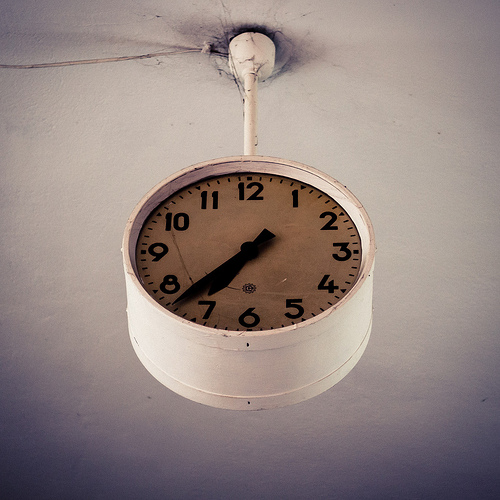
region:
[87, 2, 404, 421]
a white clock hanging from ceiling.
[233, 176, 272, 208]
number "twelve" showing on clock.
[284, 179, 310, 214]
number "one" showing on clock.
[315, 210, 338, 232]
number "two" showing on clock.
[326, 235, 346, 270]
number "three" showing on clock.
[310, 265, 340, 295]
number "four" showing on clock.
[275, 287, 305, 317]
number "five" showing on clock.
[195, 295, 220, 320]
number "seven" showing on clock.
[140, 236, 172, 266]
number "nine" showing on clock.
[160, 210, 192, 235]
number "ten" showing on clock.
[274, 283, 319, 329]
the number five in black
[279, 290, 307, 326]
the number five in black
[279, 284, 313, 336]
the number five in black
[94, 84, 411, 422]
a large white clock hanging from ceiling.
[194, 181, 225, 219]
the number "eleven" showing on clock.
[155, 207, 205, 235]
the number "ten" showing on clock.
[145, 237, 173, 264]
the number "nine" showing on clock.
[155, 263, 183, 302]
the number "eight" showing on clock.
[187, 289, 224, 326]
the number "seven" showing on clock.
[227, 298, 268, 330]
the number "six" showing on clock.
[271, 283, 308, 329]
the number "five" showing on clock.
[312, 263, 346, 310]
the number "four" showing on clock.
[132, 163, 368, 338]
the round face of a clock.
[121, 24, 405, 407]
A white clock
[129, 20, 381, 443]
A white clock hanging from the ceiling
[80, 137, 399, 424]
A round white clock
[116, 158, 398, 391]
A white clock with black hands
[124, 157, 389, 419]
A white clock with black numbers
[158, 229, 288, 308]
the hands of a clock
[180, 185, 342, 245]
the numbers of a clock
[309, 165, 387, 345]
the edge of a clock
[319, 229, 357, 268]
A black number "3"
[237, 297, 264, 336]
A black number "6"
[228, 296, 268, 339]
number six in black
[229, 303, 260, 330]
number six in black